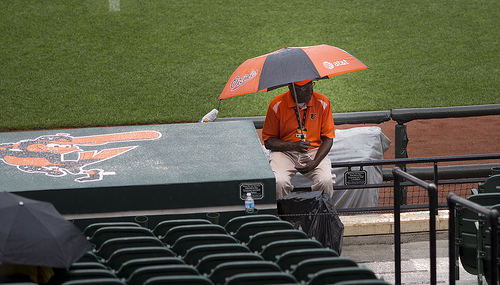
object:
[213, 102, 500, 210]
railing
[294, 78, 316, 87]
hat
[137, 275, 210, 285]
seats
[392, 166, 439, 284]
rail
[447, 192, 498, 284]
rail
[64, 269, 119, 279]
seats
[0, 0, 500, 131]
green field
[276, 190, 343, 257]
cart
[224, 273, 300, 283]
seats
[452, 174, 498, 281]
seats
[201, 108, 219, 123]
bottle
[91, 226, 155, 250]
folding chairs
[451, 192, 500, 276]
folding chairs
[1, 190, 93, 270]
black umbrella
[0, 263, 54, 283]
fan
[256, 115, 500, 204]
dirt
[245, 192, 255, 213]
bottle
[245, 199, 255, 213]
water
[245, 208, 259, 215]
holder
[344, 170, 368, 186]
signs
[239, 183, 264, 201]
signs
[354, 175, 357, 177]
words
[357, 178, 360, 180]
words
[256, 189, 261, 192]
words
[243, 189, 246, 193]
words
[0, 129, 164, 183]
logo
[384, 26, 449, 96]
grass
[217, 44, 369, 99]
umbrella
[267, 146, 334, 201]
pants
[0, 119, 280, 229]
dugout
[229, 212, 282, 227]
seat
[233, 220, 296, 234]
seat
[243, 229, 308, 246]
seat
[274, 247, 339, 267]
seat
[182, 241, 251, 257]
seat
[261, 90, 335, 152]
shirt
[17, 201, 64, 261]
black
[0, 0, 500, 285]
stadium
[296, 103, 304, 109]
white undershirt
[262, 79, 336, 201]
man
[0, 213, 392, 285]
stands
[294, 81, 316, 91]
glasses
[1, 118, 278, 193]
roof